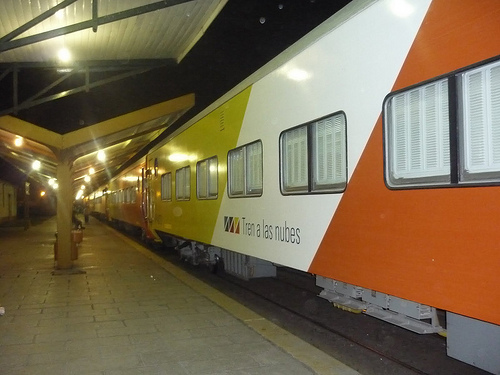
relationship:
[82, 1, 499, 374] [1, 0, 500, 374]
train at train station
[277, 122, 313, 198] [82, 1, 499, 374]
window on train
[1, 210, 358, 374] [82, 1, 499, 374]
sidewalk next to train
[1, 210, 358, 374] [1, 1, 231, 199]
sidewalk has an awning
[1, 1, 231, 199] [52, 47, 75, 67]
awning has a light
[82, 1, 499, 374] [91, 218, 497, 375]
train on tracks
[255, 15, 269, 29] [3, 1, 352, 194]
moon in sky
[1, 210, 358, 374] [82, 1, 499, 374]
sidewalk beside train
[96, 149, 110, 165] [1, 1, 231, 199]
light on awning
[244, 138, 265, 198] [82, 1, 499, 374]
window on train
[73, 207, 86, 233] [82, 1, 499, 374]
person waiting for train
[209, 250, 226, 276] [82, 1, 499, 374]
wheel on train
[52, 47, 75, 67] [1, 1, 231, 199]
light hanging from awning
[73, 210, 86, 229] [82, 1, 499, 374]
person are waiting for train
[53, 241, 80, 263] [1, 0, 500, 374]
bench under train station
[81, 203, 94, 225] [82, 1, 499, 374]
person walking to train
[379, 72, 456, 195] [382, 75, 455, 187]
window has window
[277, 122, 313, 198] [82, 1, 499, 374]
window alongside train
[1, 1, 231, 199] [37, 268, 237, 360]
awning of platform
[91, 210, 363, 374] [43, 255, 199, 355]
line of platform